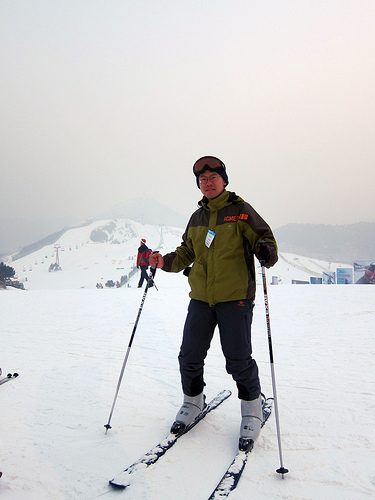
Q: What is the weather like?
A: It is cloudy.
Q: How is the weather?
A: It is cloudy.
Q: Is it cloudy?
A: Yes, it is cloudy.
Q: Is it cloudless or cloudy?
A: It is cloudy.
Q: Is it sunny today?
A: No, it is cloudy.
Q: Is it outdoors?
A: Yes, it is outdoors.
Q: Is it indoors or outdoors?
A: It is outdoors.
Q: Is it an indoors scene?
A: No, it is outdoors.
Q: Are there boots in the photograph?
A: Yes, there are boots.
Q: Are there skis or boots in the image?
A: Yes, there are boots.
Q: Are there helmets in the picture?
A: No, there are no helmets.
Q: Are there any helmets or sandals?
A: No, there are no helmets or sandals.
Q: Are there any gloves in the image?
A: Yes, there are gloves.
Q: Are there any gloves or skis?
A: Yes, there are gloves.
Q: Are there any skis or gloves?
A: Yes, there are gloves.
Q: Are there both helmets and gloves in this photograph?
A: No, there are gloves but no helmets.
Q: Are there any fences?
A: No, there are no fences.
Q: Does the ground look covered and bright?
A: Yes, the ground is covered and bright.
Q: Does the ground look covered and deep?
A: Yes, the ground is covered and deep.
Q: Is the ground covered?
A: Yes, the ground is covered.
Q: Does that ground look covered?
A: Yes, the ground is covered.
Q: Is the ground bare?
A: No, the ground is covered.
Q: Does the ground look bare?
A: No, the ground is covered.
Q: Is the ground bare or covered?
A: The ground is covered.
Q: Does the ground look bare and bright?
A: No, the ground is bright but covered.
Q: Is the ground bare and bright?
A: No, the ground is bright but covered.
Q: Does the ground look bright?
A: Yes, the ground is bright.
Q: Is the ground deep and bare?
A: No, the ground is deep but covered.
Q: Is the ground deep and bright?
A: Yes, the ground is deep and bright.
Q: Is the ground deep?
A: Yes, the ground is deep.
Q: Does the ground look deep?
A: Yes, the ground is deep.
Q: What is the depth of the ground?
A: The ground is deep.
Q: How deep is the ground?
A: The ground is deep.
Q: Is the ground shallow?
A: No, the ground is deep.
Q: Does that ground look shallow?
A: No, the ground is deep.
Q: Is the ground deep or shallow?
A: The ground is deep.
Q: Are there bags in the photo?
A: No, there are no bags.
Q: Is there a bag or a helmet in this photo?
A: No, there are no bags or helmets.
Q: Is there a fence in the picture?
A: No, there are no fences.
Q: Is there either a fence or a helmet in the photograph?
A: No, there are no fences or helmets.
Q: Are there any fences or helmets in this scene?
A: No, there are no fences or helmets.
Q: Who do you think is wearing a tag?
A: The man is wearing a tag.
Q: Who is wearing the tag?
A: The man is wearing a tag.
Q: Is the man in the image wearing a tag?
A: Yes, the man is wearing a tag.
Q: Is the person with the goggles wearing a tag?
A: Yes, the man is wearing a tag.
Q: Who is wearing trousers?
A: The man is wearing trousers.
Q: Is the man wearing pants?
A: Yes, the man is wearing pants.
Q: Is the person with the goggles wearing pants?
A: Yes, the man is wearing pants.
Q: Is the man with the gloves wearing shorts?
A: No, the man is wearing pants.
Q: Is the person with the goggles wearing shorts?
A: No, the man is wearing pants.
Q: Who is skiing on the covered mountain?
A: The man is skiing on the mountain.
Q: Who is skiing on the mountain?
A: The man is skiing on the mountain.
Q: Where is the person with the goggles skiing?
A: The man is skiing on the mountain.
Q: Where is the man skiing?
A: The man is skiing on the mountain.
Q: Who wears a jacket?
A: The man wears a jacket.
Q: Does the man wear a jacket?
A: Yes, the man wears a jacket.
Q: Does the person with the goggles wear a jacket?
A: Yes, the man wears a jacket.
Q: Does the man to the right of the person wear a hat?
A: No, the man wears a jacket.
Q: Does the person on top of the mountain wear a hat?
A: No, the man wears a jacket.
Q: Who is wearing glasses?
A: The man is wearing glasses.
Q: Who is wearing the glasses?
A: The man is wearing glasses.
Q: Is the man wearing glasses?
A: Yes, the man is wearing glasses.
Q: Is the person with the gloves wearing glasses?
A: Yes, the man is wearing glasses.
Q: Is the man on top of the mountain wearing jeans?
A: No, the man is wearing glasses.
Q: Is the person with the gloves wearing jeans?
A: No, the man is wearing glasses.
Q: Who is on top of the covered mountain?
A: The man is on top of the mountain.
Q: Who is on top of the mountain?
A: The man is on top of the mountain.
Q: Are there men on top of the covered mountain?
A: Yes, there is a man on top of the mountain.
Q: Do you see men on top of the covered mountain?
A: Yes, there is a man on top of the mountain.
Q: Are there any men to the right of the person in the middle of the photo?
A: Yes, there is a man to the right of the person.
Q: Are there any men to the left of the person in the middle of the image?
A: No, the man is to the right of the person.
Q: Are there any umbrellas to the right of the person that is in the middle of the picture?
A: No, there is a man to the right of the person.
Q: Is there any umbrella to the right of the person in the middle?
A: No, there is a man to the right of the person.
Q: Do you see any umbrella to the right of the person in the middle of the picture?
A: No, there is a man to the right of the person.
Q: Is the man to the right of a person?
A: Yes, the man is to the right of a person.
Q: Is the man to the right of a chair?
A: No, the man is to the right of a person.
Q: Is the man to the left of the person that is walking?
A: No, the man is to the right of the person.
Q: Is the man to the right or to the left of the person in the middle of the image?
A: The man is to the right of the person.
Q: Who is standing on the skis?
A: The man is standing on the skis.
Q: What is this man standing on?
A: The man is standing on the skis.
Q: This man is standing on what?
A: The man is standing on the skis.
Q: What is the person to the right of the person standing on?
A: The man is standing on the skis.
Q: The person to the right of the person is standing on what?
A: The man is standing on the skis.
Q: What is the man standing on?
A: The man is standing on the skis.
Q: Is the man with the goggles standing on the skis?
A: Yes, the man is standing on the skis.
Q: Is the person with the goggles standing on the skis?
A: Yes, the man is standing on the skis.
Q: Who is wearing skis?
A: The man is wearing skis.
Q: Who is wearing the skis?
A: The man is wearing skis.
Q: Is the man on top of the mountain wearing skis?
A: Yes, the man is wearing skis.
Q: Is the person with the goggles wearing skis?
A: Yes, the man is wearing skis.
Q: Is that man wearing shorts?
A: No, the man is wearing skis.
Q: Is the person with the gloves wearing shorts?
A: No, the man is wearing skis.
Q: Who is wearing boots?
A: The man is wearing boots.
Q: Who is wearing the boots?
A: The man is wearing boots.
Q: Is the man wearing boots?
A: Yes, the man is wearing boots.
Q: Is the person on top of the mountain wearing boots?
A: Yes, the man is wearing boots.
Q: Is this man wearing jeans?
A: No, the man is wearing boots.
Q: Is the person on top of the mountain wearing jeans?
A: No, the man is wearing boots.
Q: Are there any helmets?
A: No, there are no helmets.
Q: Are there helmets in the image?
A: No, there are no helmets.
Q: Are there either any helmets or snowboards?
A: No, there are no helmets or snowboards.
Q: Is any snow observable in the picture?
A: Yes, there is snow.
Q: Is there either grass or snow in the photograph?
A: Yes, there is snow.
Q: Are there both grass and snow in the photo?
A: No, there is snow but no grass.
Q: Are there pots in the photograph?
A: No, there are no pots.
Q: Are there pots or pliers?
A: No, there are no pots or pliers.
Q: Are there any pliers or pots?
A: No, there are no pots or pliers.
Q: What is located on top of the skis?
A: The snow is on top of the skis.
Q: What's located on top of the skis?
A: The snow is on top of the skis.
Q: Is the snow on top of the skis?
A: Yes, the snow is on top of the skis.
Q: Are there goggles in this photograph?
A: Yes, there are goggles.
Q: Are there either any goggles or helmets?
A: Yes, there are goggles.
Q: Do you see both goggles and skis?
A: Yes, there are both goggles and skis.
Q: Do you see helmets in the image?
A: No, there are no helmets.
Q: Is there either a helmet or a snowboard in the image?
A: No, there are no helmets or snowboards.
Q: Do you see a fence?
A: No, there are no fences.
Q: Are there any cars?
A: No, there are no cars.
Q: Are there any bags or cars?
A: No, there are no cars or bags.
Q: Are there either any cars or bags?
A: No, there are no cars or bags.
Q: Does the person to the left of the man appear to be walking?
A: Yes, the person is walking.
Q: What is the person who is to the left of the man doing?
A: The person is walking.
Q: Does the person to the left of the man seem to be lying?
A: No, the person is walking.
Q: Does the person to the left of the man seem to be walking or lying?
A: The person is walking.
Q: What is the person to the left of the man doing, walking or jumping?
A: The person is walking.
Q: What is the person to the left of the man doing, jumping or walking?
A: The person is walking.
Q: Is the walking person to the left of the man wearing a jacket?
A: Yes, the person is wearing a jacket.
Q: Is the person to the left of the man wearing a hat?
A: No, the person is wearing a jacket.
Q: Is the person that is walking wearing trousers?
A: Yes, the person is wearing trousers.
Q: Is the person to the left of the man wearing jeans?
A: No, the person is wearing trousers.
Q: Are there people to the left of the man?
A: Yes, there is a person to the left of the man.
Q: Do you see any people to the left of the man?
A: Yes, there is a person to the left of the man.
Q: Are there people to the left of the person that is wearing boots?
A: Yes, there is a person to the left of the man.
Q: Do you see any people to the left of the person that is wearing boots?
A: Yes, there is a person to the left of the man.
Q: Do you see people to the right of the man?
A: No, the person is to the left of the man.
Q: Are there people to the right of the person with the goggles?
A: No, the person is to the left of the man.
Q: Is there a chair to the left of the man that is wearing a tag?
A: No, there is a person to the left of the man.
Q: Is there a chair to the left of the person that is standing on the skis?
A: No, there is a person to the left of the man.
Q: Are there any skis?
A: Yes, there are skis.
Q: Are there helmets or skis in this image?
A: Yes, there are skis.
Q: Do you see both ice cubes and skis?
A: No, there are skis but no ice cubes.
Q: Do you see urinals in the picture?
A: No, there are no urinals.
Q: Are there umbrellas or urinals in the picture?
A: No, there are no urinals or umbrellas.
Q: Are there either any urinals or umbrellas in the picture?
A: No, there are no urinals or umbrellas.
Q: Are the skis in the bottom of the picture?
A: Yes, the skis are in the bottom of the image.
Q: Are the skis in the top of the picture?
A: No, the skis are in the bottom of the image.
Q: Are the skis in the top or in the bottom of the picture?
A: The skis are in the bottom of the image.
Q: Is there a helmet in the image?
A: No, there are no helmets.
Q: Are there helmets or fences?
A: No, there are no helmets or fences.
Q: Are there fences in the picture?
A: No, there are no fences.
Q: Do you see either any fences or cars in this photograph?
A: No, there are no fences or cars.